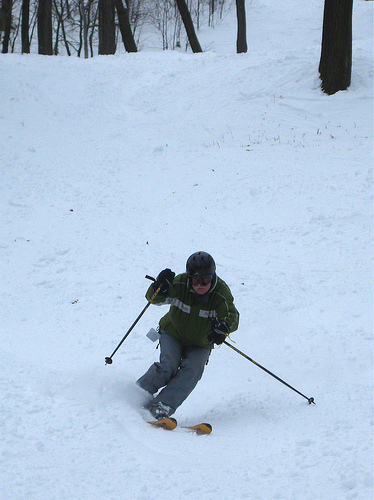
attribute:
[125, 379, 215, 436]
skies — orange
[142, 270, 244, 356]
jacket — green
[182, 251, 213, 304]
helmet — black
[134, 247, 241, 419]
skier — going down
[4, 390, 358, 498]
snow — white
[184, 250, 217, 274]
helmet — black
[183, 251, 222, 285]
helmet — black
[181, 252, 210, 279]
helmet — black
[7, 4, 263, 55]
trees — in background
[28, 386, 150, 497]
snow — white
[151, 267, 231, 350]
gloves — black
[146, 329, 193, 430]
pants — grey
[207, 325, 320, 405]
pole — black, yellow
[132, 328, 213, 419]
pants — grey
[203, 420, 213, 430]
tip — black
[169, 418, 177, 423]
tip — black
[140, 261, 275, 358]
jacket — green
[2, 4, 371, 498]
ground — sloppy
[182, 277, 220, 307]
beard — white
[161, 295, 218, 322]
stripe — grey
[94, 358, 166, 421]
snow — flying up